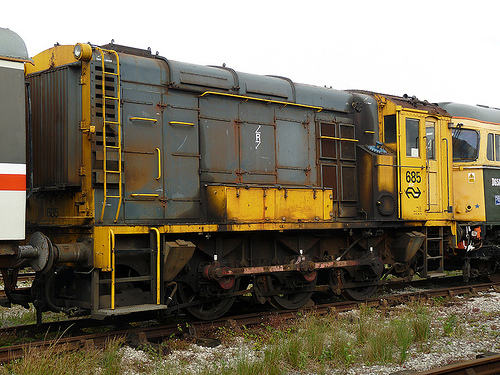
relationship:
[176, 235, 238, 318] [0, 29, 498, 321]
wheel on train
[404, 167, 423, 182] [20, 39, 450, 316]
685 on traincar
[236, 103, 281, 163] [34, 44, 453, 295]
design on traincar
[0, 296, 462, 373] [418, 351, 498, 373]
grass between tracks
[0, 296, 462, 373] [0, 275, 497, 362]
grass between tracks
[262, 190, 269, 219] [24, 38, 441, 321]
rust on car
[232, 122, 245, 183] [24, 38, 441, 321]
rust on car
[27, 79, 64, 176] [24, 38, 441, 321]
rust on car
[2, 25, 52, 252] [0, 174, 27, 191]
train car has stripe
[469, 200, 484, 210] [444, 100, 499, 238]
star on train car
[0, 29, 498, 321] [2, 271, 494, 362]
train on track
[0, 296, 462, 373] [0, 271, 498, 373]
grass between tracks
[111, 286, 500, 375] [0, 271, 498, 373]
gravel between tracks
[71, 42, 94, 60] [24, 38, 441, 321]
light on top of car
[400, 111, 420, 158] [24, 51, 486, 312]
window on train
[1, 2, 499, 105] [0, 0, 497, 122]
clouds in sky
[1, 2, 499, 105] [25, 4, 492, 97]
clouds in sky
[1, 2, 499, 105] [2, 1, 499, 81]
clouds in sky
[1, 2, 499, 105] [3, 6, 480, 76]
clouds in sky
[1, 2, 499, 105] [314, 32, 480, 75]
clouds in sky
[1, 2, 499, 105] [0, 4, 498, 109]
clouds in sky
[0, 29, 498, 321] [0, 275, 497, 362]
train on tracks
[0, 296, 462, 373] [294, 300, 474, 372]
grass growing in gravel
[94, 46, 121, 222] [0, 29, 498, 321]
ladder on train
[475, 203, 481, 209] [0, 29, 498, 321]
star on train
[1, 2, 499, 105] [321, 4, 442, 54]
clouds in sky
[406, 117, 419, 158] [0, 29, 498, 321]
window on train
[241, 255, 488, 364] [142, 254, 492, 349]
gravel beside tracks